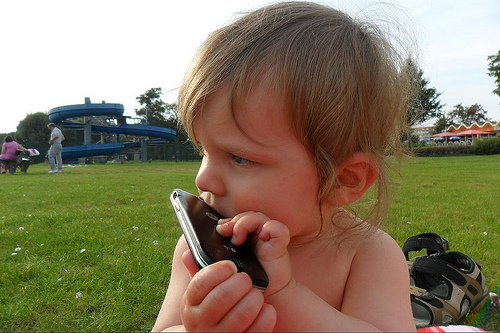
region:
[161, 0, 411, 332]
The boy biting a cell phone.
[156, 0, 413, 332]
The boy sitting alone.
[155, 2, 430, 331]
The boy has blonde hair.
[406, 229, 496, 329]
A pair of beige sandals.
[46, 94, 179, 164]
Blue water slide.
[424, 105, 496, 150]
A store selling tickets and snacks.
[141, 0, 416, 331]
A boy wearing no clothes.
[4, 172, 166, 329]
Green grass suitable for picnics.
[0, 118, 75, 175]
A man and a woman talking to each other.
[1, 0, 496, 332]
A public park belongs to the town.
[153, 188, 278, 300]
A smart phone in a girls hand.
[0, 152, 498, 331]
a field of green grass.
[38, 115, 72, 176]
an adult standing in a field.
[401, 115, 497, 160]
a canopy at a park.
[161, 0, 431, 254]
short brown hair.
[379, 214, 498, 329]
personal item on the ground.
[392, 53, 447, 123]
a tall green tree.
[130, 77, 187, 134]
a tall tree in a park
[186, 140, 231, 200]
a baby nose.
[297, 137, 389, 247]
a baby ear.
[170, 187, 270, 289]
small black cell phone partially in the mouth of a toddler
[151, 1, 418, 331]
a small toddler outside with their mouth partially covering a small phone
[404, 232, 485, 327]
a pair of brown sandals sitting on the grown outside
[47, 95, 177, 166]
large blue spiral water slide at a park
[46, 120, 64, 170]
man in light clothing standing not far from a spiral water slide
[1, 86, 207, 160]
large area covered with various trees and colored dark green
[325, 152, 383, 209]
left ear of a small toddler mouthing a small phone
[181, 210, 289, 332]
small toddler hands holding a cell phone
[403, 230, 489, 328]
large sandals with camouflage coloring sitting on the ground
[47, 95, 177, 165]
water slide with spiral shape and a blue color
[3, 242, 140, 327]
many grass in the field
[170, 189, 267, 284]
a black smartphone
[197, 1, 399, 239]
the head of the kid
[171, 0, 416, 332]
the kid biting the smartphone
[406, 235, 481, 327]
a pair of sandals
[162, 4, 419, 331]
a blond kid with a smartphone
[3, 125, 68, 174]
two people talking in the distance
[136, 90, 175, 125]
green branches of the tree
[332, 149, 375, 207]
one ear of the kid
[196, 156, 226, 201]
the nose of the child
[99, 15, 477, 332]
a kid that is outside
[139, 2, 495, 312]
a child that is outside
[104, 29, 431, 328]
a young child outside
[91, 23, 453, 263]
a kid with blond hair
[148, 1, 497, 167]
a child with blonde hair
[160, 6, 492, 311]
a young child with blonde hair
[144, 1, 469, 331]
a kid with a phone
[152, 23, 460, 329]
a child with a phone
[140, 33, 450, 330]
a young child with a phone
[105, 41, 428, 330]
a child chewing on a phone